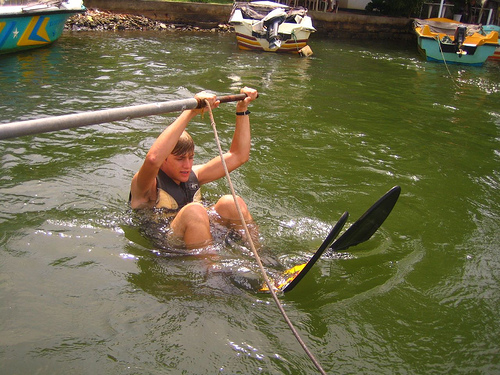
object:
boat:
[0, 0, 87, 55]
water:
[5, 30, 498, 374]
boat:
[411, 17, 499, 67]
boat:
[228, 0, 317, 53]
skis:
[231, 220, 404, 296]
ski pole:
[0, 94, 259, 139]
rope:
[204, 99, 326, 374]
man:
[128, 86, 283, 297]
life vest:
[128, 170, 202, 231]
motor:
[455, 25, 467, 56]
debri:
[65, 7, 234, 33]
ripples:
[2, 39, 498, 372]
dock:
[85, 0, 499, 59]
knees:
[184, 201, 207, 221]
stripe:
[427, 56, 483, 67]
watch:
[235, 109, 250, 116]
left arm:
[197, 105, 251, 181]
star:
[11, 28, 20, 37]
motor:
[262, 7, 288, 53]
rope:
[437, 35, 460, 91]